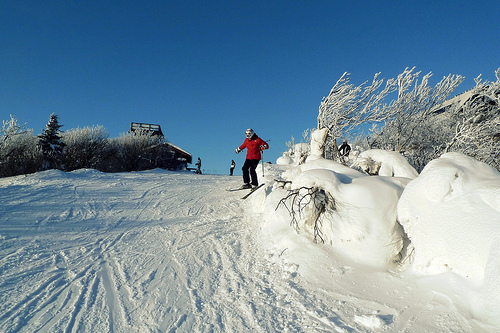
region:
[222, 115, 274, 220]
skier in red jacket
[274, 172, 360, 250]
plant roots poking out of snow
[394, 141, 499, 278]
piles of white powdery snow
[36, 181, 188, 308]
ski tracks in the snow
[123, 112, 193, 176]
structure on side of ski trail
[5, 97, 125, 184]
trees topped with snow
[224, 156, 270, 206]
black pants on skier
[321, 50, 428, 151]
light snow on branches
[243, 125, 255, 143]
skier wearing safety helmet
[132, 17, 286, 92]
clear sky with no clouds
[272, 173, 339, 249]
Snow covered branch.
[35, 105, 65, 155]
Big green pine tree.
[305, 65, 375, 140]
Large frozen tree.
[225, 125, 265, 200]
Person in red skiing.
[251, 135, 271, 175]
Ski pole for skiing.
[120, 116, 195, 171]
Large ski resort on top of the hill.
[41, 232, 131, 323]
Ski tracks in the snow.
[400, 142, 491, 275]
Large pile of snow.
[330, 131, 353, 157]
Person skiing in the trees.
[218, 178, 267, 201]
Black pair of skiis.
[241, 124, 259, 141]
the head of a man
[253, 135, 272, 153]
the arm of a man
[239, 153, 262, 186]
a pair of black pants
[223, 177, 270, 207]
a pair of skis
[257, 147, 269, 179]
a black ski pole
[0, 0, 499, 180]
a clear blue sky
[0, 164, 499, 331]
white snow on the ground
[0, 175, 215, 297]
the shadows on the ground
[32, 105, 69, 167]
a small green tree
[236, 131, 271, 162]
a red coat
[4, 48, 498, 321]
a ski slope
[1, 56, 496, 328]
a snowy ski slope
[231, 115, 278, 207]
a person with a red coat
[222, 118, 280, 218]
a person on skis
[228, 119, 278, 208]
the person in red is skiing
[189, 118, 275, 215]
people on the slope are sking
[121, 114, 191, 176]
a building is a the top of the ski slope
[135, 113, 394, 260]
the skiiers are on a hill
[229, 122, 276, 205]
the person on the skis has a red coat on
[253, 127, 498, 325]
snow is gathered against the bushes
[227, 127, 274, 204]
a man skiing down hill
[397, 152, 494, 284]
a large snow mound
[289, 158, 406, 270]
a large snow mound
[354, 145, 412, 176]
a large snow mound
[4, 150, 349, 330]
a snowy hill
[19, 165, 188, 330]
ski tracks on snowy hill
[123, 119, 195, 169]
a building at top of hill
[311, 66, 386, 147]
a tree covered in snow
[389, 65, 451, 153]
a tree covered in snow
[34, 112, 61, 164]
a tree covered in snow